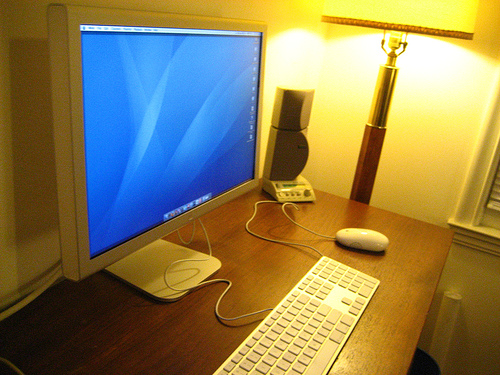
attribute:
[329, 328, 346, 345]
button — white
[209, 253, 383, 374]
keyboard — slim, white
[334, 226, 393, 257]
mouse — white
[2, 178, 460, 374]
desk — brown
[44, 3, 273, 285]
monitor — white, computer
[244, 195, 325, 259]
cord — white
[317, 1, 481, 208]
lamp — chrome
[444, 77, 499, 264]
window — white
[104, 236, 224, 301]
stand — white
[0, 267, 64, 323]
wire — white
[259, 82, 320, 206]
speaker — gray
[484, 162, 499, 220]
blinds — white